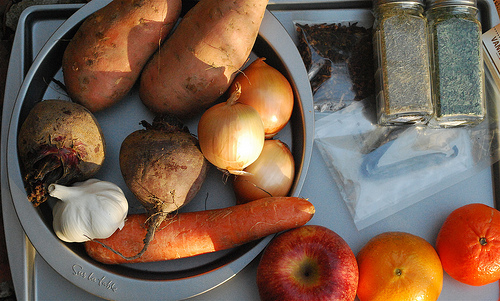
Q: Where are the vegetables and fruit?
A: On the tray.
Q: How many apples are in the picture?
A: One.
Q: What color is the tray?
A: Silver.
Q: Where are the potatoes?
A: In the cake pan.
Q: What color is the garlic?
A: White.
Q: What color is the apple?
A: Red.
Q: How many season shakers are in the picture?
A: Two.